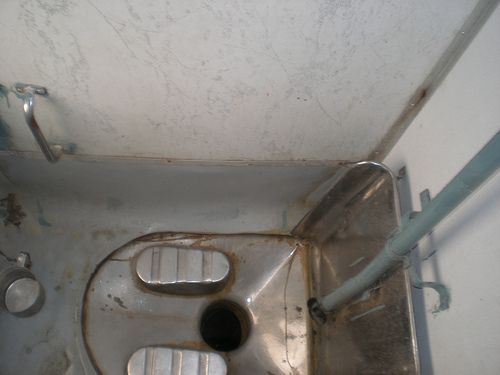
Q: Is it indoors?
A: Yes, it is indoors.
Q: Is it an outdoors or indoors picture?
A: It is indoors.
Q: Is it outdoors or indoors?
A: It is indoors.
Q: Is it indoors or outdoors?
A: It is indoors.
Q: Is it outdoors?
A: No, it is indoors.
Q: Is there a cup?
A: Yes, there is a cup.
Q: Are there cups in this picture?
A: Yes, there is a cup.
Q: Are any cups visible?
A: Yes, there is a cup.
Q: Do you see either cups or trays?
A: Yes, there is a cup.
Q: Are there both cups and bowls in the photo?
A: No, there is a cup but no bowls.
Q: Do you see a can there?
A: No, there are no cans.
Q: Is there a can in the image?
A: No, there are no cans.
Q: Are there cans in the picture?
A: No, there are no cans.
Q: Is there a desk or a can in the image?
A: No, there are no cans or desks.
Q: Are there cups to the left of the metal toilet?
A: Yes, there is a cup to the left of the toilet.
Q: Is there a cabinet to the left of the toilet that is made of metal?
A: No, there is a cup to the left of the toilet.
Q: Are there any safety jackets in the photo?
A: No, there are no safety jackets.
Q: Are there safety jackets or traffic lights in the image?
A: No, there are no safety jackets or traffic lights.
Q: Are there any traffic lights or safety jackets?
A: No, there are no safety jackets or traffic lights.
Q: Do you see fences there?
A: No, there are no fences.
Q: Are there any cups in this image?
A: Yes, there is a cup.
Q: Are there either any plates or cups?
A: Yes, there is a cup.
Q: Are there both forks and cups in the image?
A: No, there is a cup but no forks.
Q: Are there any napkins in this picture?
A: No, there are no napkins.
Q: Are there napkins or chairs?
A: No, there are no napkins or chairs.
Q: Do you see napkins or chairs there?
A: No, there are no napkins or chairs.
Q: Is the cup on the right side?
A: No, the cup is on the left of the image.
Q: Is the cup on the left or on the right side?
A: The cup is on the left of the image.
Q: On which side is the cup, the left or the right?
A: The cup is on the left of the image.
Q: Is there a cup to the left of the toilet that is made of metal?
A: Yes, there is a cup to the left of the toilet.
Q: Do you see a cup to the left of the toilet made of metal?
A: Yes, there is a cup to the left of the toilet.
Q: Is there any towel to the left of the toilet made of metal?
A: No, there is a cup to the left of the toilet.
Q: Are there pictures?
A: No, there are no pictures.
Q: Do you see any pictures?
A: No, there are no pictures.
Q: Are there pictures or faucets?
A: No, there are no pictures or faucets.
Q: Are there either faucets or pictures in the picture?
A: No, there are no pictures or faucets.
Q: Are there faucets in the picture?
A: No, there are no faucets.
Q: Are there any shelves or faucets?
A: No, there are no faucets or shelves.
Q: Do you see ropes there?
A: No, there are no ropes.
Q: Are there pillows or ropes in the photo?
A: No, there are no ropes or pillows.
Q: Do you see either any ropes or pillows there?
A: No, there are no ropes or pillows.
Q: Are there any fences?
A: No, there are no fences.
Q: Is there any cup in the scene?
A: Yes, there is a cup.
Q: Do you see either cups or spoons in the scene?
A: Yes, there is a cup.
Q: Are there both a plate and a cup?
A: No, there is a cup but no plates.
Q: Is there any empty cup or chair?
A: Yes, there is an empty cup.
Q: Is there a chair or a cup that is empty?
A: Yes, the cup is empty.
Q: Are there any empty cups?
A: Yes, there is an empty cup.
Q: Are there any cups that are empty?
A: Yes, there is a cup that is empty.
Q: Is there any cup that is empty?
A: Yes, there is a cup that is empty.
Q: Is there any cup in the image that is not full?
A: Yes, there is a empty cup.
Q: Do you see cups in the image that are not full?
A: Yes, there is a empty cup.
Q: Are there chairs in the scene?
A: No, there are no chairs.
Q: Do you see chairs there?
A: No, there are no chairs.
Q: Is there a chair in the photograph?
A: No, there are no chairs.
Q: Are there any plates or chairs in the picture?
A: No, there are no chairs or plates.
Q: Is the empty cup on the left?
A: Yes, the cup is on the left of the image.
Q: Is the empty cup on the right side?
A: No, the cup is on the left of the image.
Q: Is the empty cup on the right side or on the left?
A: The cup is on the left of the image.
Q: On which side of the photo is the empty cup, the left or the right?
A: The cup is on the left of the image.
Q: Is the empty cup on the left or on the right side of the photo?
A: The cup is on the left of the image.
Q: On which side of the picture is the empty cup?
A: The cup is on the left of the image.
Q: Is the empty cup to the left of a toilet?
A: Yes, the cup is to the left of a toilet.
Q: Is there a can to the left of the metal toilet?
A: No, there is a cup to the left of the toilet.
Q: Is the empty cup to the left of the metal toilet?
A: Yes, the cup is to the left of the toilet.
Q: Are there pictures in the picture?
A: No, there are no pictures.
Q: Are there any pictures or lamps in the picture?
A: No, there are no pictures or lamps.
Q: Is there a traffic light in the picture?
A: No, there are no traffic lights.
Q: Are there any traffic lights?
A: No, there are no traffic lights.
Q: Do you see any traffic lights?
A: No, there are no traffic lights.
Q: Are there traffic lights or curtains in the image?
A: No, there are no traffic lights or curtains.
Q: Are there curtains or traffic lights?
A: No, there are no traffic lights or curtains.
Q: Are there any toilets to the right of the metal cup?
A: Yes, there is a toilet to the right of the cup.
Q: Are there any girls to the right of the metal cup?
A: No, there is a toilet to the right of the cup.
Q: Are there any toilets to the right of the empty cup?
A: Yes, there is a toilet to the right of the cup.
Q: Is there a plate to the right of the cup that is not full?
A: No, there is a toilet to the right of the cup.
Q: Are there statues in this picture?
A: No, there are no statues.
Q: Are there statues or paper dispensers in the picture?
A: No, there are no statues or paper dispensers.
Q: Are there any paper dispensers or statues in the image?
A: No, there are no statues or paper dispensers.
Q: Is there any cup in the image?
A: Yes, there is a cup.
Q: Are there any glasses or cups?
A: Yes, there is a cup.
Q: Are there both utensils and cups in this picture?
A: No, there is a cup but no utensils.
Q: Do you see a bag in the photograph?
A: No, there are no bags.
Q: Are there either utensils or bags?
A: No, there are no bags or utensils.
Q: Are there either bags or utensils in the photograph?
A: No, there are no bags or utensils.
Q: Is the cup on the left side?
A: Yes, the cup is on the left of the image.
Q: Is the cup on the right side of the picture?
A: No, the cup is on the left of the image.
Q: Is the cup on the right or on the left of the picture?
A: The cup is on the left of the image.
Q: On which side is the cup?
A: The cup is on the left of the image.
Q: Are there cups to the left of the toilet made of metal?
A: Yes, there is a cup to the left of the toilet.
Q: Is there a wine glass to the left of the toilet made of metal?
A: No, there is a cup to the left of the toilet.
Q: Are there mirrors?
A: No, there are no mirrors.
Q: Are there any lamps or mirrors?
A: No, there are no mirrors or lamps.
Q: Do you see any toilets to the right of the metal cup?
A: Yes, there is a toilet to the right of the cup.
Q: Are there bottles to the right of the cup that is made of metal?
A: No, there is a toilet to the right of the cup.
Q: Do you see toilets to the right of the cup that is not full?
A: Yes, there is a toilet to the right of the cup.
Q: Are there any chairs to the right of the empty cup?
A: No, there is a toilet to the right of the cup.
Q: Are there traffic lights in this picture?
A: No, there are no traffic lights.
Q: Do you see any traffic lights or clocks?
A: No, there are no traffic lights or clocks.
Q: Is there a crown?
A: No, there are no crowns.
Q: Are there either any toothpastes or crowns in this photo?
A: No, there are no crowns or toothpastes.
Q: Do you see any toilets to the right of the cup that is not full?
A: Yes, there is a toilet to the right of the cup.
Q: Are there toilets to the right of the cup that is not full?
A: Yes, there is a toilet to the right of the cup.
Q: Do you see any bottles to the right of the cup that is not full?
A: No, there is a toilet to the right of the cup.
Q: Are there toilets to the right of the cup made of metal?
A: Yes, there is a toilet to the right of the cup.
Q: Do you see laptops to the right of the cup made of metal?
A: No, there is a toilet to the right of the cup.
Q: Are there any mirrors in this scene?
A: No, there are no mirrors.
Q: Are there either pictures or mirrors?
A: No, there are no mirrors or pictures.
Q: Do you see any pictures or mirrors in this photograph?
A: No, there are no mirrors or pictures.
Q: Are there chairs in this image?
A: No, there are no chairs.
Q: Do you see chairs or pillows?
A: No, there are no chairs or pillows.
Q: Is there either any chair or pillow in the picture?
A: No, there are no chairs or pillows.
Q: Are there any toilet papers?
A: No, there are no toilet papers.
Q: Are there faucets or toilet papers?
A: No, there are no toilet papers or faucets.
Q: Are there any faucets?
A: No, there are no faucets.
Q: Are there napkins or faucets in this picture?
A: No, there are no faucets or napkins.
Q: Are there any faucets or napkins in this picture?
A: No, there are no faucets or napkins.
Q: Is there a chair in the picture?
A: No, there are no chairs.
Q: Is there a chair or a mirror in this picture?
A: No, there are no chairs or mirrors.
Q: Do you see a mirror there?
A: No, there are no mirrors.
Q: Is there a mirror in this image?
A: No, there are no mirrors.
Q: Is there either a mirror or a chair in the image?
A: No, there are no mirrors or chairs.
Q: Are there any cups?
A: Yes, there is a cup.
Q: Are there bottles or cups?
A: Yes, there is a cup.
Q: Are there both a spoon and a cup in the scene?
A: No, there is a cup but no spoons.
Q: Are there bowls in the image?
A: No, there are no bowls.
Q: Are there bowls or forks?
A: No, there are no bowls or forks.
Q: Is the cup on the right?
A: No, the cup is on the left of the image.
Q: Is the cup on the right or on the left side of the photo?
A: The cup is on the left of the image.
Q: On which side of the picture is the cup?
A: The cup is on the left of the image.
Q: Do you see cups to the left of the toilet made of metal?
A: Yes, there is a cup to the left of the toilet.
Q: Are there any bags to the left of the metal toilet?
A: No, there is a cup to the left of the toilet.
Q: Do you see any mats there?
A: No, there are no mats.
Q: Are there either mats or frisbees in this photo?
A: No, there are no mats or frisbees.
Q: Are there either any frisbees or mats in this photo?
A: No, there are no mats or frisbees.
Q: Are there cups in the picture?
A: Yes, there is a cup.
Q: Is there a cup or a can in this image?
A: Yes, there is a cup.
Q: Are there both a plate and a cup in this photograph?
A: No, there is a cup but no plates.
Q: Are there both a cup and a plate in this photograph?
A: No, there is a cup but no plates.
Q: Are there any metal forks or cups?
A: Yes, there is a metal cup.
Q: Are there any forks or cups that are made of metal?
A: Yes, the cup is made of metal.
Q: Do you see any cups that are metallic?
A: Yes, there is a metal cup.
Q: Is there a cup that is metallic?
A: Yes, there is a cup that is metallic.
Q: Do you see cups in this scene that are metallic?
A: Yes, there is a cup that is metallic.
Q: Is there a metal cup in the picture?
A: Yes, there is a cup that is made of metal.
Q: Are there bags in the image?
A: No, there are no bags.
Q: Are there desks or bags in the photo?
A: No, there are no bags or desks.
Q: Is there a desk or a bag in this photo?
A: No, there are no bags or desks.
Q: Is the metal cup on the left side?
A: Yes, the cup is on the left of the image.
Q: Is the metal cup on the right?
A: No, the cup is on the left of the image.